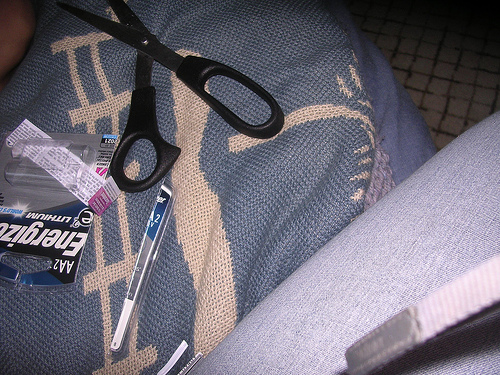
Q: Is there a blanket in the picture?
A: Yes, there is a blanket.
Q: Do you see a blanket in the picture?
A: Yes, there is a blanket.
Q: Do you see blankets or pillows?
A: Yes, there is a blanket.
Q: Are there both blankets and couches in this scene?
A: No, there is a blanket but no couches.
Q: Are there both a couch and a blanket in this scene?
A: No, there is a blanket but no couches.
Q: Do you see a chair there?
A: No, there are no chairs.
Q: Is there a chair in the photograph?
A: No, there are no chairs.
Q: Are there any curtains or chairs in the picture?
A: No, there are no chairs or curtains.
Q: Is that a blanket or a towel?
A: That is a blanket.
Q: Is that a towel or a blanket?
A: That is a blanket.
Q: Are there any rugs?
A: No, there are no rugs.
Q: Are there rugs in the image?
A: No, there are no rugs.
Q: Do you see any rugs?
A: No, there are no rugs.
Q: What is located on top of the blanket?
A: The scissors are on top of the blanket.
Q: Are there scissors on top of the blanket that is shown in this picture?
A: Yes, there are scissors on top of the blanket.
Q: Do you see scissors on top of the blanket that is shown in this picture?
A: Yes, there are scissors on top of the blanket.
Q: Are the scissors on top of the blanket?
A: Yes, the scissors are on top of the blanket.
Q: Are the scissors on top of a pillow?
A: No, the scissors are on top of the blanket.